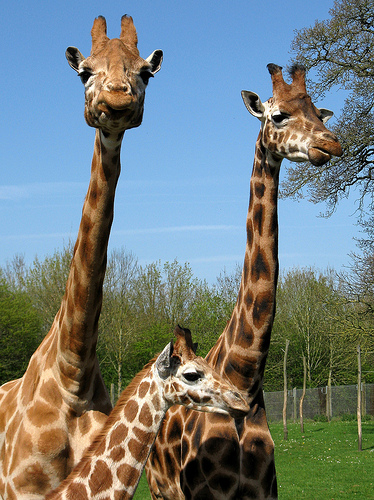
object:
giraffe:
[143, 61, 342, 499]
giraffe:
[41, 324, 250, 500]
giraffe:
[0, 14, 163, 500]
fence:
[262, 383, 373, 423]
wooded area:
[0, 235, 373, 450]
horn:
[290, 64, 307, 92]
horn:
[266, 63, 286, 89]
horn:
[173, 324, 185, 348]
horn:
[182, 328, 194, 349]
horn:
[120, 14, 138, 48]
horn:
[91, 15, 107, 49]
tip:
[289, 64, 306, 74]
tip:
[267, 63, 281, 75]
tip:
[182, 327, 192, 334]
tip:
[174, 324, 184, 336]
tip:
[121, 14, 132, 23]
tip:
[94, 14, 106, 22]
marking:
[253, 181, 265, 200]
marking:
[245, 217, 254, 252]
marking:
[249, 244, 271, 284]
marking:
[252, 289, 273, 330]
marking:
[243, 289, 253, 312]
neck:
[203, 141, 282, 400]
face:
[77, 55, 155, 128]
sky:
[0, 1, 373, 322]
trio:
[0, 13, 344, 499]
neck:
[43, 367, 174, 500]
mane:
[43, 351, 161, 499]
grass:
[132, 414, 373, 499]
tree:
[277, 0, 373, 218]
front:
[201, 391, 278, 500]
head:
[240, 62, 342, 167]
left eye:
[136, 69, 154, 85]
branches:
[327, 193, 373, 352]